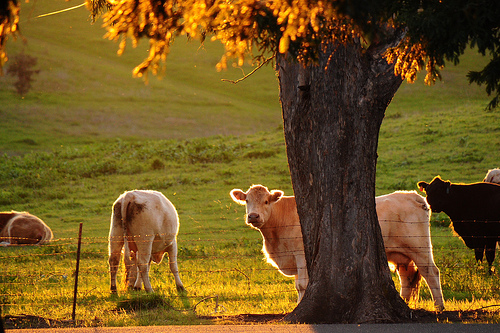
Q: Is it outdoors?
A: Yes, it is outdoors.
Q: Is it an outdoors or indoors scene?
A: It is outdoors.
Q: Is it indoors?
A: No, it is outdoors.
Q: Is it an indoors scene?
A: No, it is outdoors.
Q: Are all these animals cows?
A: Yes, all the animals are cows.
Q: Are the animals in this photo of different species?
A: No, all the animals are cows.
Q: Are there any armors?
A: No, there are no armors.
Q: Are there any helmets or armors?
A: No, there are no armors or helmets.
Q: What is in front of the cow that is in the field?
A: The wire is in front of the cow.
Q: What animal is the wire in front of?
A: The wire is in front of the cow.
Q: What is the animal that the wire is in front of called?
A: The animal is a cow.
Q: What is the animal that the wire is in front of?
A: The animal is a cow.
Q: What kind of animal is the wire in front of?
A: The wire is in front of the cow.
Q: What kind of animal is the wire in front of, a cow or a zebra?
A: The wire is in front of a cow.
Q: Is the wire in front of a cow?
A: Yes, the wire is in front of a cow.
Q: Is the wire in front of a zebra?
A: No, the wire is in front of a cow.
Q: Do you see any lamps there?
A: No, there are no lamps.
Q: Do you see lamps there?
A: No, there are no lamps.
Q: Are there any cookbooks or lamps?
A: No, there are no lamps or cookbooks.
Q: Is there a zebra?
A: No, there are no zebras.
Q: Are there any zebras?
A: No, there are no zebras.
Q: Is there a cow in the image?
A: Yes, there is a cow.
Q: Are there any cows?
A: Yes, there is a cow.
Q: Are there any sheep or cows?
A: Yes, there is a cow.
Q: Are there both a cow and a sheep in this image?
A: No, there is a cow but no sheep.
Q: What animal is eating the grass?
A: The cow is eating the grass.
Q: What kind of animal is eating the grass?
A: The animal is a cow.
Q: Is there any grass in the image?
A: Yes, there is grass.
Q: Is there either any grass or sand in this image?
A: Yes, there is grass.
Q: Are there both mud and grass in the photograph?
A: No, there is grass but no mud.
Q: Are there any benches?
A: No, there are no benches.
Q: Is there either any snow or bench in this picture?
A: No, there are no benches or snow.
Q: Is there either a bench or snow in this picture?
A: No, there are no benches or snow.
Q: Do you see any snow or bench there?
A: No, there are no benches or snow.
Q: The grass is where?
A: The grass is on the ground.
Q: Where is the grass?
A: The grass is on the ground.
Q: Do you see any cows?
A: Yes, there is a cow.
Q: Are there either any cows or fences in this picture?
A: Yes, there is a cow.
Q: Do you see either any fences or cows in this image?
A: Yes, there is a cow.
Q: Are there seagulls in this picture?
A: No, there are no seagulls.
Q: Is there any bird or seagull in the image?
A: No, there are no seagulls or birds.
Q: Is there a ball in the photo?
A: No, there are no balls.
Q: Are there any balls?
A: No, there are no balls.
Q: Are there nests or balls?
A: No, there are no balls or nests.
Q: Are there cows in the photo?
A: Yes, there is a cow.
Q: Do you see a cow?
A: Yes, there is a cow.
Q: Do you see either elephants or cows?
A: Yes, there is a cow.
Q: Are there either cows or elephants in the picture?
A: Yes, there is a cow.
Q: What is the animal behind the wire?
A: The animal is a cow.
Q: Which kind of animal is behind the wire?
A: The animal is a cow.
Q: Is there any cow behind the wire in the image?
A: Yes, there is a cow behind the wire.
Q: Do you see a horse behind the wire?
A: No, there is a cow behind the wire.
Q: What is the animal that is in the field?
A: The animal is a cow.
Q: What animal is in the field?
A: The animal is a cow.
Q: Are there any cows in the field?
A: Yes, there is a cow in the field.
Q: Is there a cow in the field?
A: Yes, there is a cow in the field.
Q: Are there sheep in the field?
A: No, there is a cow in the field.